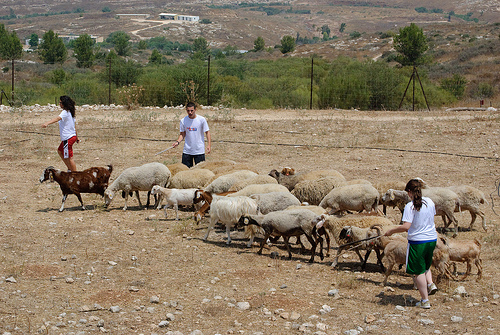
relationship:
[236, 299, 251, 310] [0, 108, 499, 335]
rock on dirt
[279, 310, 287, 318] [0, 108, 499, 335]
rock on dirt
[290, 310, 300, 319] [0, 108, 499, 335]
rock on dirt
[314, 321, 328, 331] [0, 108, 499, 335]
rock on dirt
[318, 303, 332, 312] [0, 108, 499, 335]
rock on dirt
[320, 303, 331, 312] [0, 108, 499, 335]
rock on dirt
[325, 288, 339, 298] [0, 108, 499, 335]
rock on dirt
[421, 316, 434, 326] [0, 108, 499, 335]
rock on dirt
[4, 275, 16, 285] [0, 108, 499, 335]
rock on dirt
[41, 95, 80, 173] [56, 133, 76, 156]
person wearing shorts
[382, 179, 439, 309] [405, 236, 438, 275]
people wearing shorts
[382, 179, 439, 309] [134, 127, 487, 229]
people herding goats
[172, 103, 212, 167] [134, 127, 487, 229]
person herding goats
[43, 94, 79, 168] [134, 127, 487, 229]
person herding goats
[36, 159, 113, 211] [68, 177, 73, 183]
goat with spot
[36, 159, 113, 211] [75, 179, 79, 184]
goat with spot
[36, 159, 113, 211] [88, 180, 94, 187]
goat with spot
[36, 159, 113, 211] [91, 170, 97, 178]
goat with spot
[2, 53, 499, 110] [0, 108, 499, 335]
fence enclosing dirt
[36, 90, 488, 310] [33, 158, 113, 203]
people hearding goat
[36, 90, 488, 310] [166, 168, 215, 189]
people hearding goat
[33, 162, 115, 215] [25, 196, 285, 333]
goat walking in dirt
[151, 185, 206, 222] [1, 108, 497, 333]
goat walking in dirt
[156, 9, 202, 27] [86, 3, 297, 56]
house on hill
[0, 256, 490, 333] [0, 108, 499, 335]
rocks on dirt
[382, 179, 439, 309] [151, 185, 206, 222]
people herding goat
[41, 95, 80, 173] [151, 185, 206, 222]
person herding goat